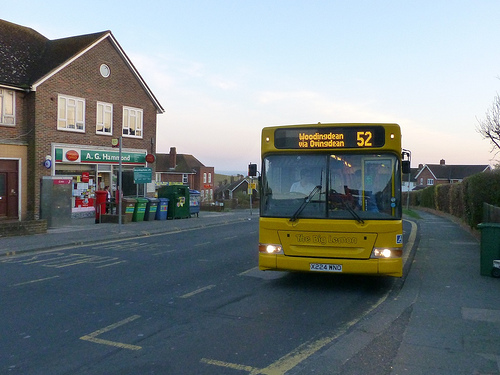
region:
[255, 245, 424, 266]
the lights are on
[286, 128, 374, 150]
nthere is a number 52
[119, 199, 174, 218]
there are four trash bins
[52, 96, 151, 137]
there are three windows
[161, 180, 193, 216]
the trash container is blue in color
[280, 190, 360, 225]
there is wipers on the windshield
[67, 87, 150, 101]
the wall is made of bricks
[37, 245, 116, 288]
there is a stop sign on road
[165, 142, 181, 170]
there is a brick chimney on the roof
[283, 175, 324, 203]
the driver has white top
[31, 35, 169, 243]
A store.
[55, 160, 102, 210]
The window is covered in flyers and posters.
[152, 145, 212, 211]
A brick building in the background.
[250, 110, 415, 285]
A yellow bus.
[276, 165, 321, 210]
The bus driver is in the driver's seat.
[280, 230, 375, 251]
The name of the bus.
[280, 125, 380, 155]
The bus' route and route number.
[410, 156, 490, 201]
A home in the distance.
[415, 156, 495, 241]
A hedge runs parallel to the sidewalk.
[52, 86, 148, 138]
Three large windows.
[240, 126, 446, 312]
The bus is a bright yellow.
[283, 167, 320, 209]
The driver is sitting on the bus.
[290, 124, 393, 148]
The bus sign is on.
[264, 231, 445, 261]
The headlights on the bus are turned on.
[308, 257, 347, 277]
The car tag is in black letters.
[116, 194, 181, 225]
The recycling bins are in front of the store.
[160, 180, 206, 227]
A dumpster sits in front of the store.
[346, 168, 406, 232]
A person stepping onto the bus.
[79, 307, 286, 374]
The street has yellow lines.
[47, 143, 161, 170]
The sign above the store is green.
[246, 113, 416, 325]
the bus is yellow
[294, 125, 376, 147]
the bus' number is 52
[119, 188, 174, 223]
thrash bins in front of the store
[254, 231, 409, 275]
the headlights are turned on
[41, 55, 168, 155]
the house is brown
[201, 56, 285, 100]
the sky is white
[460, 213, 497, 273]
the trash bin is green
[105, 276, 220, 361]
the street is gray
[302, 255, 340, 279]
the plate number is white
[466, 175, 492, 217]
the bush is green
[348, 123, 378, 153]
A YELLOW NUMBER 52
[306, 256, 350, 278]
A LICENSE PLATE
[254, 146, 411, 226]
BUS WIND SHIELD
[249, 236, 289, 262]
HEADLIGHT ON A BUS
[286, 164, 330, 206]
BUS DRIVER SITTING AT THE WHEEL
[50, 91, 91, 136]
WINDOW ON A BRICK BUILDING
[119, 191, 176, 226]
GARBAGE CANS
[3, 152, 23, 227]
A BROWN WOODEN DOOR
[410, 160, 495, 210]
A HOUSE IN THE BACKGROUND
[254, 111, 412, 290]
A YELLOW COMMUTER BUS